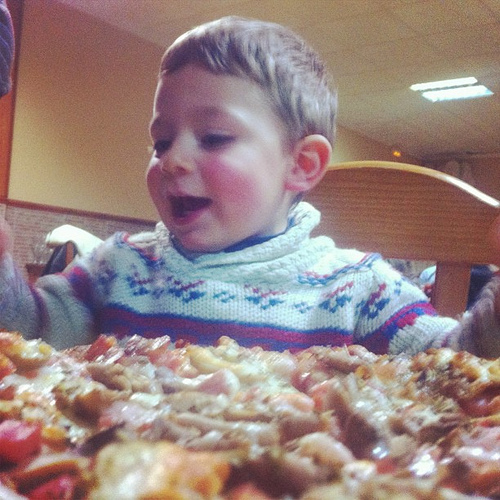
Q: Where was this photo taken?
A: In a restaurant.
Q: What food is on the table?
A: A pizza.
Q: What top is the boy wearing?
A: A sweater.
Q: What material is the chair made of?
A: Wood.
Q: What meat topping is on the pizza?
A: Sausage.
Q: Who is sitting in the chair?
A: A boy.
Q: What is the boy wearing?
A: Sweater.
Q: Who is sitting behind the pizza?
A: A boy.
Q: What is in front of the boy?
A: Pizza.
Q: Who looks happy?
A: The boy.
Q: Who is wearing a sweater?
A: The boy.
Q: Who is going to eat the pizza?
A: The boy.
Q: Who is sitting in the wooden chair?
A: The boy.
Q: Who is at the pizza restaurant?
A: The boy.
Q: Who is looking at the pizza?
A: The boy.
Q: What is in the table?
A: Pizza.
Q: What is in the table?
A: Food.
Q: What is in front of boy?
A: Food.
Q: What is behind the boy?
A: Wall.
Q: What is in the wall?
A: Tiles.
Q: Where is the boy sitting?
A: Chair.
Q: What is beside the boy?
A: Wall.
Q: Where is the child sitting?
A: Chair.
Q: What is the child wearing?
A: Sweater.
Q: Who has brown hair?
A: The boy.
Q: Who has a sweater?
A: The boy.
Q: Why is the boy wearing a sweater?
A: Cold weather.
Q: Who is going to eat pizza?
A: The boy.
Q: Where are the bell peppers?
A: On the pizza.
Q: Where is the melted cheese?
A: On the pizza.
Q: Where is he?
A: Restaurant.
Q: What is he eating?
A: Pizza.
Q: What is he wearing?
A: Sweater.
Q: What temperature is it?
A: Cold.